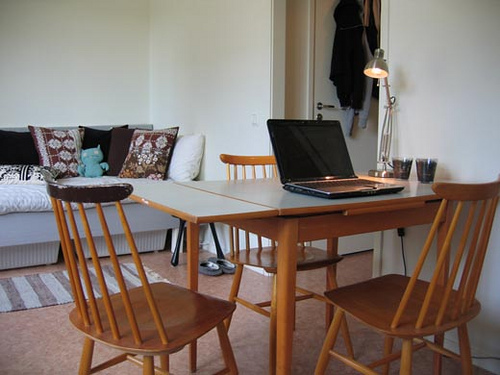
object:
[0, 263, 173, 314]
runner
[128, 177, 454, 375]
table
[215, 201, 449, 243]
wood base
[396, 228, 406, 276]
electrical cord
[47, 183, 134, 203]
black top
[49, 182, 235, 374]
chair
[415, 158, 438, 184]
cup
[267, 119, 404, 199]
lap top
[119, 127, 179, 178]
pillow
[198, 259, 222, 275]
slipper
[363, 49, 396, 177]
table lamp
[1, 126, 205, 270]
couch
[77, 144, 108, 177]
stuffed animal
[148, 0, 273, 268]
wall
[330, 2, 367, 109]
sweatshirt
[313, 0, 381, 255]
door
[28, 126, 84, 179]
pillow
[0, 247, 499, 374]
floor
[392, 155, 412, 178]
cup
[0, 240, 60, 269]
container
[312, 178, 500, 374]
chair